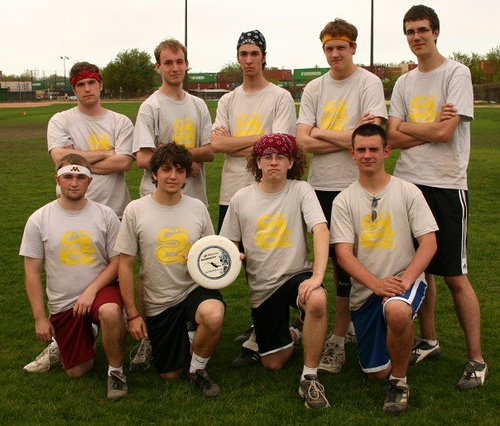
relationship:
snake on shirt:
[160, 229, 185, 276] [111, 191, 221, 340]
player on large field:
[209, 26, 298, 231] [1, 105, 498, 422]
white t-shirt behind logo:
[24, 207, 118, 297] [56, 225, 95, 266]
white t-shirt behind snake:
[112, 194, 217, 317] [156, 228, 190, 265]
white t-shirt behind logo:
[230, 182, 318, 275] [253, 209, 291, 253]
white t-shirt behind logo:
[338, 182, 421, 279] [359, 210, 393, 254]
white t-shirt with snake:
[112, 194, 219, 317] [156, 228, 190, 265]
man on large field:
[329, 124, 439, 411] [1, 105, 498, 422]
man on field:
[216, 135, 333, 413] [237, 348, 338, 423]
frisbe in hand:
[183, 232, 242, 290] [238, 250, 245, 260]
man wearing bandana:
[216, 135, 333, 413] [248, 135, 301, 161]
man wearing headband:
[18, 153, 130, 403] [46, 166, 106, 185]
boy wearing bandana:
[45, 60, 132, 217] [70, 70, 101, 87]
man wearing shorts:
[18, 153, 130, 403] [34, 286, 124, 391]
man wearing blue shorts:
[329, 124, 439, 411] [350, 270, 427, 371]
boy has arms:
[45, 60, 132, 217] [53, 140, 130, 171]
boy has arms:
[130, 40, 212, 209] [135, 140, 215, 176]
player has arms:
[209, 31, 298, 232] [210, 120, 282, 159]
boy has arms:
[290, 17, 393, 217] [292, 118, 362, 156]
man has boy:
[382, 4, 489, 392] [45, 60, 132, 217]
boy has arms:
[45, 60, 132, 217] [387, 106, 464, 146]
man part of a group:
[329, 124, 439, 411] [20, 4, 491, 417]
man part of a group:
[216, 135, 333, 413] [20, 4, 491, 417]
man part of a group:
[382, 4, 489, 392] [20, 4, 491, 417]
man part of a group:
[113, 142, 224, 402] [20, 4, 491, 417]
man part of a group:
[18, 153, 130, 403] [20, 4, 491, 417]